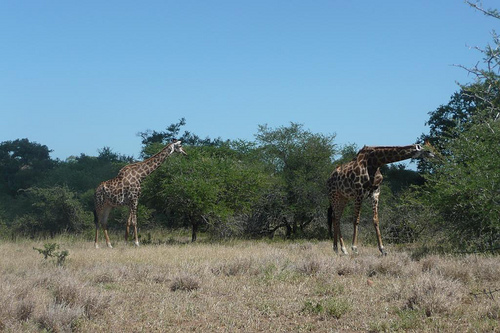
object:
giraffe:
[324, 138, 434, 257]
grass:
[8, 294, 35, 326]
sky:
[382, 9, 473, 25]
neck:
[367, 138, 422, 174]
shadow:
[369, 152, 384, 161]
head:
[159, 129, 196, 162]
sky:
[27, 15, 74, 90]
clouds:
[49, 22, 217, 84]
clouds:
[321, 29, 463, 91]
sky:
[8, 22, 33, 73]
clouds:
[12, 12, 68, 50]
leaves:
[240, 136, 305, 212]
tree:
[162, 117, 313, 235]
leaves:
[186, 143, 208, 161]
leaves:
[467, 82, 500, 120]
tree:
[406, 60, 487, 258]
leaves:
[485, 152, 500, 195]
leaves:
[44, 156, 85, 190]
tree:
[18, 129, 94, 207]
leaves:
[0, 150, 18, 170]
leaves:
[455, 100, 476, 131]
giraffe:
[75, 123, 178, 236]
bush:
[29, 239, 69, 267]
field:
[62, 237, 343, 316]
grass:
[196, 308, 222, 333]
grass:
[383, 280, 428, 316]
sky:
[89, 17, 139, 57]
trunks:
[270, 205, 316, 243]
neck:
[125, 148, 169, 180]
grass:
[289, 311, 310, 331]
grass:
[289, 312, 304, 330]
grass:
[206, 251, 227, 271]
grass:
[146, 309, 168, 324]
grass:
[179, 261, 259, 318]